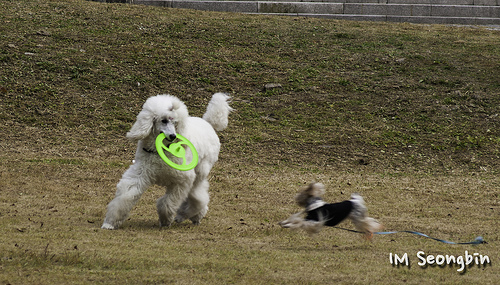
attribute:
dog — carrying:
[111, 128, 196, 130]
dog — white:
[95, 93, 250, 250]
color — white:
[192, 126, 207, 144]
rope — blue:
[324, 215, 479, 248]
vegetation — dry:
[0, 198, 248, 282]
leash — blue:
[344, 202, 484, 255]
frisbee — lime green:
[136, 134, 196, 177]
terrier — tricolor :
[281, 177, 382, 239]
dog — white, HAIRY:
[100, 84, 232, 226]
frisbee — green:
[153, 130, 202, 173]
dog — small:
[275, 178, 382, 242]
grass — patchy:
[0, 0, 497, 282]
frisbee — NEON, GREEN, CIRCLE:
[155, 135, 193, 168]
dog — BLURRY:
[293, 182, 378, 241]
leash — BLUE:
[400, 225, 459, 248]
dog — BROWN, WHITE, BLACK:
[299, 180, 376, 250]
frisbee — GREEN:
[145, 127, 205, 169]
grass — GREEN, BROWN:
[254, 198, 274, 260]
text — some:
[384, 238, 500, 277]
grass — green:
[21, 33, 444, 84]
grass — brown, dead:
[24, 225, 498, 267]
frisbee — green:
[148, 127, 202, 170]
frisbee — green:
[153, 130, 213, 176]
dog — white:
[104, 72, 234, 218]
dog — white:
[99, 91, 245, 232]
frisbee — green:
[150, 123, 200, 183]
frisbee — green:
[160, 131, 195, 182]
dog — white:
[118, 83, 235, 213]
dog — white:
[95, 96, 237, 225]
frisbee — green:
[152, 126, 196, 173]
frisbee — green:
[158, 132, 207, 183]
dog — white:
[96, 74, 232, 224]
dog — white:
[109, 89, 237, 235]